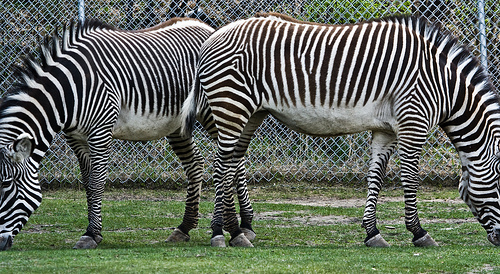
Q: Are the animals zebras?
A: Yes, all the animals are zebras.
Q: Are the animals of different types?
A: No, all the animals are zebras.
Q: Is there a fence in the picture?
A: Yes, there is a fence.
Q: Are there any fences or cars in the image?
A: Yes, there is a fence.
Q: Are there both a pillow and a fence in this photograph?
A: No, there is a fence but no pillows.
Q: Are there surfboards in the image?
A: No, there are no surfboards.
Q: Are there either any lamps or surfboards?
A: No, there are no surfboards or lamps.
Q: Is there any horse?
A: No, there are no horses.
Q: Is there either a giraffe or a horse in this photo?
A: No, there are no horses or giraffes.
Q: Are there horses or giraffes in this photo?
A: No, there are no horses or giraffes.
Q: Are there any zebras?
A: Yes, there is a zebra.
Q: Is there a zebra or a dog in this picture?
A: Yes, there is a zebra.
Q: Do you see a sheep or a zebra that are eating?
A: Yes, the zebra is eating.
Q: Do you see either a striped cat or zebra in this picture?
A: Yes, there is a striped zebra.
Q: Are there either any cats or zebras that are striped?
A: Yes, the zebra is striped.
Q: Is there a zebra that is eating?
A: Yes, there is a zebra that is eating.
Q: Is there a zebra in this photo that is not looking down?
A: Yes, there is a zebra that is eating.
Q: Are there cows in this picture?
A: No, there are no cows.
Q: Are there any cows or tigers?
A: No, there are no cows or tigers.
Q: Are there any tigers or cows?
A: No, there are no cows or tigers.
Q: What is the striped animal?
A: The animal is a zebra.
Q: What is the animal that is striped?
A: The animal is a zebra.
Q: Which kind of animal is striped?
A: The animal is a zebra.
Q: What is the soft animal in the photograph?
A: The animal is a zebra.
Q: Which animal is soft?
A: The animal is a zebra.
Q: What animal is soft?
A: The animal is a zebra.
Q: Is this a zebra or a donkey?
A: This is a zebra.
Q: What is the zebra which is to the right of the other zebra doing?
A: The zebra is eating.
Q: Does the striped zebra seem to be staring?
A: No, the zebra is eating.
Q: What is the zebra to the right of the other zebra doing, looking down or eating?
A: The zebra is eating.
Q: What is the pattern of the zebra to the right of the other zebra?
A: The zebra is striped.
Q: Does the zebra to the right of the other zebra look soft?
A: Yes, the zebra is soft.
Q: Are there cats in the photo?
A: No, there are no cats.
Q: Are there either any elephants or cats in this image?
A: No, there are no cats or elephants.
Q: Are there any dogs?
A: No, there are no dogs.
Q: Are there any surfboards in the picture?
A: No, there are no surfboards.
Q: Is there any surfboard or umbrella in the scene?
A: No, there are no surfboards or umbrellas.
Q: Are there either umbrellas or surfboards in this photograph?
A: No, there are no surfboards or umbrellas.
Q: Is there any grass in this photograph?
A: Yes, there is grass.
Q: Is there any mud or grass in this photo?
A: Yes, there is grass.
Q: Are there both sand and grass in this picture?
A: No, there is grass but no sand.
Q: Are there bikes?
A: No, there are no bikes.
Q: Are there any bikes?
A: No, there are no bikes.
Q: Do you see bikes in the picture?
A: No, there are no bikes.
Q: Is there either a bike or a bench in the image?
A: No, there are no bikes or benches.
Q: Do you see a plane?
A: No, there are no airplanes.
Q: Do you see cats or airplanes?
A: No, there are no airplanes or cats.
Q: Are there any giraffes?
A: No, there are no giraffes.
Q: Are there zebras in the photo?
A: Yes, there is a zebra.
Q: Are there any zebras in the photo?
A: Yes, there is a zebra.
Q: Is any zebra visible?
A: Yes, there is a zebra.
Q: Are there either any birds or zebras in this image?
A: Yes, there is a zebra.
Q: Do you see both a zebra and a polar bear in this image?
A: No, there is a zebra but no polar bears.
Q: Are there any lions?
A: No, there are no lions.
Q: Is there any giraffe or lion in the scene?
A: No, there are no lions or giraffes.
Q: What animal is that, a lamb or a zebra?
A: That is a zebra.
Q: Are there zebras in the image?
A: Yes, there are zebras.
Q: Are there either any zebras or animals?
A: Yes, there are zebras.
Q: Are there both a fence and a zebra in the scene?
A: Yes, there are both a zebra and a fence.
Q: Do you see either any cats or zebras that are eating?
A: Yes, the zebras are eating.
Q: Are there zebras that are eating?
A: Yes, there are zebras that are eating.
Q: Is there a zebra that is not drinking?
A: Yes, there are zebras that are eating.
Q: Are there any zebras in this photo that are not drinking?
A: Yes, there are zebras that are eating.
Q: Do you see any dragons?
A: No, there are no dragons.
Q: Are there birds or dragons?
A: No, there are no dragons or birds.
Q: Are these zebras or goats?
A: These are zebras.